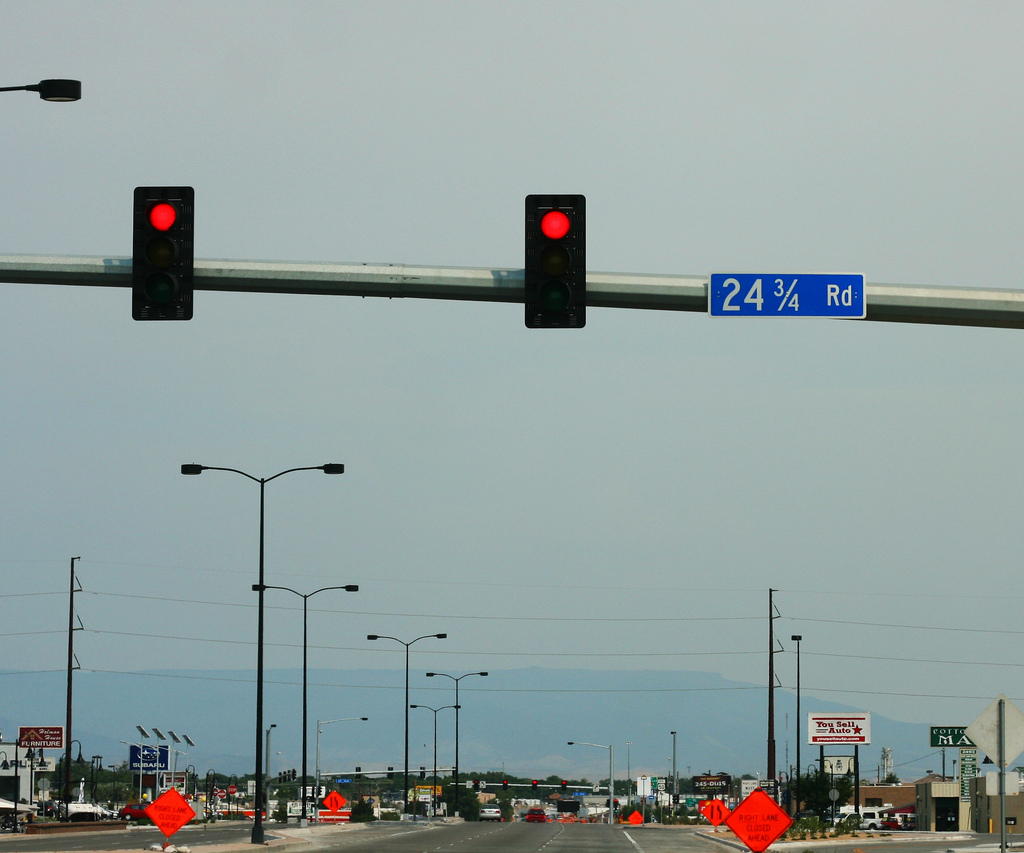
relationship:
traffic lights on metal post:
[498, 167, 629, 335] [5, 167, 1023, 335]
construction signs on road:
[707, 762, 816, 851] [407, 800, 628, 853]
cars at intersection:
[458, 791, 576, 839] [458, 756, 621, 839]